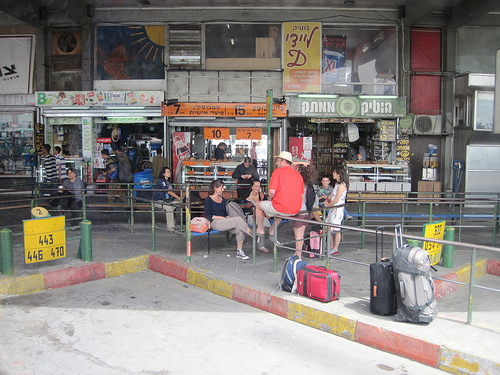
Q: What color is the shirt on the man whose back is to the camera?
A: Red.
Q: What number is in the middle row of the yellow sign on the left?
A: 443.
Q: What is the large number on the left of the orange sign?
A: 7.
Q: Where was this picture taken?
A: Bus station.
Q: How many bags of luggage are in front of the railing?
A: Four.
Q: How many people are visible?
A: 15.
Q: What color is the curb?
A: Yellow and red.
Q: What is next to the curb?
A: Luggage.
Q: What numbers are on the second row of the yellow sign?
A: 443.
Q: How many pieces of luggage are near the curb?
A: 4.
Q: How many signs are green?
A: 1.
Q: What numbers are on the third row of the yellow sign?
A: 446 470.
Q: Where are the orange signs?
A: At the shop.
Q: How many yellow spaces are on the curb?
A: 6.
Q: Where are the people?
A: At a bus station.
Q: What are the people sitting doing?
A: Waiting for a bus.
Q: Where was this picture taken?
A: The curb on the bus terminal.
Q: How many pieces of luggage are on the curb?
A: 4.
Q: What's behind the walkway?
A: Stores.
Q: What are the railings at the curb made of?
A: Metal.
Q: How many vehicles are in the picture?
A: 0.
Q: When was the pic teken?
A: During the day.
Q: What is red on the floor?
A: Suitcase.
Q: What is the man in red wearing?
A: Shorts.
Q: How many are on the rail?
A: 3.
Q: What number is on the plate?
A: 443.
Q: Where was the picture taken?
A: On the street.